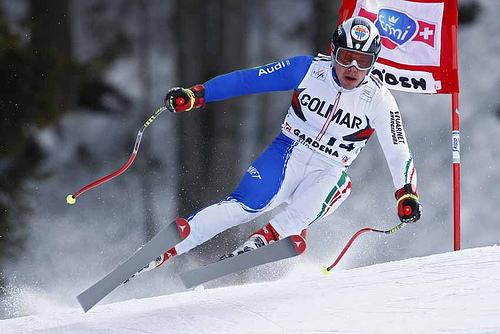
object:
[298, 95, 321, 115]
letter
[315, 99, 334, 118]
letter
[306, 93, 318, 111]
letter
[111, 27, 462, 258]
ski suit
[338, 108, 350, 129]
letter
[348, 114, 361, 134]
letter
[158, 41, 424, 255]
ski suit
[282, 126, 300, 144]
letter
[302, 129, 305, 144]
letter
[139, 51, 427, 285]
ski suit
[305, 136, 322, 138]
letter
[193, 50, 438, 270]
ski suit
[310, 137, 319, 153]
letter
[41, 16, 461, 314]
downhill skier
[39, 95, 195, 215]
ski poles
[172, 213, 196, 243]
tip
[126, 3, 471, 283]
gate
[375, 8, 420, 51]
logo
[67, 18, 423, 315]
outfit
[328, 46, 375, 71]
goggles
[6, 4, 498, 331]
race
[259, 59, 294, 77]
audi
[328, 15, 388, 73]
helmet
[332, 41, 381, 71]
googles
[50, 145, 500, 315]
turn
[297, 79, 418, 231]
white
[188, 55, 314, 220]
blue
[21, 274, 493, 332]
snow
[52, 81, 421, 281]
poles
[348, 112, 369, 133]
letter r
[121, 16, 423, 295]
athlete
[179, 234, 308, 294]
skis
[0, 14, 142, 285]
tree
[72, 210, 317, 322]
ski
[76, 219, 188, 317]
skis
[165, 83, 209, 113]
glove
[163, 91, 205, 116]
hand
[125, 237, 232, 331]
ground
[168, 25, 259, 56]
air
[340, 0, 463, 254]
flag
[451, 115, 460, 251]
pole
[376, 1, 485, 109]
sign